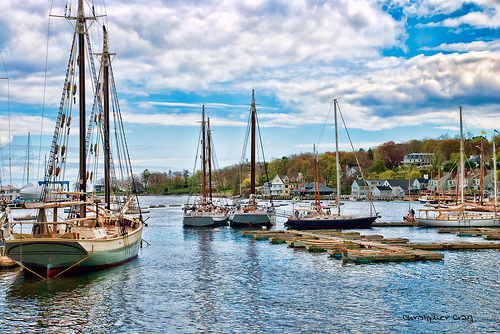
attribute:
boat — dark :
[284, 207, 382, 228]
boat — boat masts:
[22, 21, 374, 248]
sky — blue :
[408, 27, 457, 56]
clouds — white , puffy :
[1, 3, 485, 145]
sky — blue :
[0, 5, 462, 166]